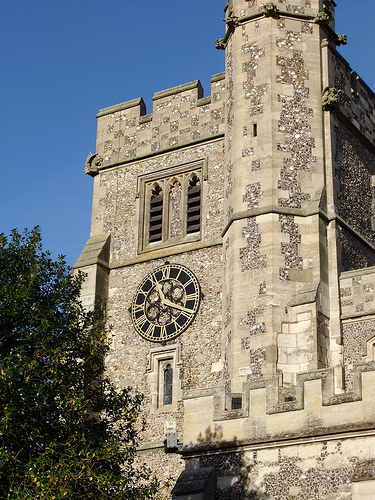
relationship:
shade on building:
[169, 414, 253, 500] [49, 9, 375, 491]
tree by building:
[4, 223, 150, 491] [49, 9, 375, 491]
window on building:
[128, 154, 208, 264] [49, 9, 375, 491]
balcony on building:
[336, 230, 375, 317] [49, 9, 375, 491]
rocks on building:
[335, 139, 371, 222] [49, 9, 375, 491]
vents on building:
[139, 177, 208, 245] [49, 9, 375, 491]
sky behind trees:
[0, 10, 127, 243] [4, 223, 150, 491]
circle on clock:
[161, 285, 186, 304] [122, 268, 210, 348]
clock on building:
[122, 268, 210, 348] [49, 9, 375, 491]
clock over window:
[122, 268, 210, 348] [148, 344, 185, 414]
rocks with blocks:
[335, 139, 371, 222] [251, 138, 322, 208]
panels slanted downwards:
[147, 191, 166, 240] [152, 195, 168, 244]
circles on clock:
[145, 293, 168, 322] [122, 268, 210, 348]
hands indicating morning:
[150, 281, 173, 306] [4, 5, 220, 87]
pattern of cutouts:
[120, 80, 249, 136] [136, 86, 159, 126]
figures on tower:
[216, 3, 285, 33] [220, 9, 342, 402]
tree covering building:
[4, 223, 150, 491] [49, 9, 375, 491]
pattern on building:
[120, 80, 249, 136] [49, 9, 375, 491]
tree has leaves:
[4, 223, 150, 491] [18, 236, 50, 271]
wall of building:
[125, 120, 284, 182] [49, 9, 375, 491]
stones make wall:
[244, 91, 302, 173] [125, 120, 284, 182]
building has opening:
[49, 9, 375, 491] [196, 73, 226, 104]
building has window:
[49, 9, 375, 491] [128, 154, 208, 264]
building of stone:
[49, 9, 375, 491] [266, 83, 307, 143]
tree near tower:
[4, 223, 150, 491] [220, 9, 342, 402]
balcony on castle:
[336, 230, 375, 317] [49, 9, 375, 491]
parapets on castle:
[88, 15, 372, 118] [49, 9, 375, 491]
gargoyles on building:
[305, 74, 349, 110] [49, 9, 375, 491]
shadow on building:
[169, 414, 253, 500] [49, 9, 375, 491]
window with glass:
[148, 344, 185, 414] [161, 366, 180, 405]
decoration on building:
[244, 216, 305, 270] [49, 9, 375, 491]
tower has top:
[220, 9, 342, 402] [222, 2, 349, 47]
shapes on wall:
[342, 277, 372, 318] [125, 120, 284, 182]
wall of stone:
[125, 120, 284, 182] [266, 83, 307, 143]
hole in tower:
[250, 118, 265, 139] [220, 9, 342, 402]